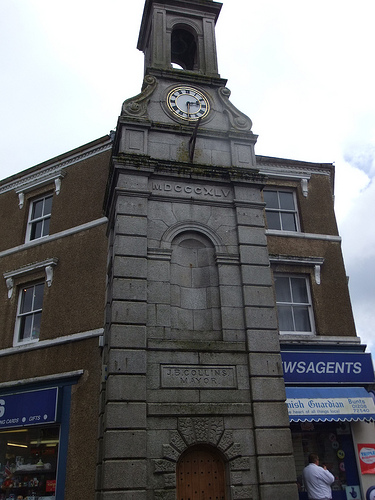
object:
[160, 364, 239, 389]
stone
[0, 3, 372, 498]
building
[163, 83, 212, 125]
clock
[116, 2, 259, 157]
clock tower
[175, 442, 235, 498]
door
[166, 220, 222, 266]
arch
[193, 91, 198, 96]
roman numerals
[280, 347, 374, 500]
shop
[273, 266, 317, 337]
window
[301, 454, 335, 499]
man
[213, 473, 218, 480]
bolts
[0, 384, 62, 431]
sign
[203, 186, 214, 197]
roman numerals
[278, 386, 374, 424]
awning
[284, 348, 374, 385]
blue sign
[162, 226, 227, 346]
alcove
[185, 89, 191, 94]
black numerals